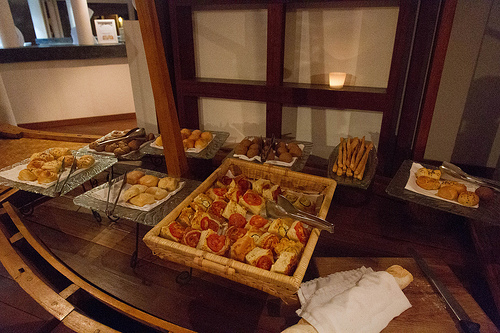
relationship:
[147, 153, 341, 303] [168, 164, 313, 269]
tray full of rolls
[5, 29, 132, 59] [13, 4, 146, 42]
counter in front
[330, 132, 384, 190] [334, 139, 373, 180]
tray of snacks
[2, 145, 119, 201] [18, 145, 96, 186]
tray of rolls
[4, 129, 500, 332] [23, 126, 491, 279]
table filled with bread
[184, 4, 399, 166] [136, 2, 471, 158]
window on wall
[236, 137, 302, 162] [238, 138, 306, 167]
brown colored bread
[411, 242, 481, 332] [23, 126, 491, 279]
knife to cut bread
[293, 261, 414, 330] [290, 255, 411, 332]
loaf of bread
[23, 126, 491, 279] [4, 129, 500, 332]
bread on table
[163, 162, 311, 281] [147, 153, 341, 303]
sandwiches in basket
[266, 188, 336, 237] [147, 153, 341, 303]
tong over basket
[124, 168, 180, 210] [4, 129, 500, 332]
baguette on table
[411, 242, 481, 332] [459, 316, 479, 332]
knife with handle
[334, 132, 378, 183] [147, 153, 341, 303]
bread behind basket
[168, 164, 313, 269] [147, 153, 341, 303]
food in basket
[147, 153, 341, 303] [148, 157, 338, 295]
basket made of wicker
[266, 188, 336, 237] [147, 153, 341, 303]
tongs in basket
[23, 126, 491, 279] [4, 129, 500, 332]
pastries on server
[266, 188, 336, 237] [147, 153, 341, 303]
tongs in server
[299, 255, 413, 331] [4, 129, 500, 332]
towel on table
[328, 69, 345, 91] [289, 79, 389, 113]
candle in shelf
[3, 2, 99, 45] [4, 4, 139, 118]
column in background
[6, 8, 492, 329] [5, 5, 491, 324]
photo was indoors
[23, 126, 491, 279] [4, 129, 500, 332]
buffet on table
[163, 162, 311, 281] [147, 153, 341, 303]
sandwiches on basket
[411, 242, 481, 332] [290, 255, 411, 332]
knife to cut bread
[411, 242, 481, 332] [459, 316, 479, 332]
knife has handle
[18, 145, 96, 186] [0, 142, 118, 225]
croissants on container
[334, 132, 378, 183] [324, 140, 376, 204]
bread on basket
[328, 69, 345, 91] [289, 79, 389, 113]
candle on shelf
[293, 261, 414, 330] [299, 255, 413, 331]
baguette with cloth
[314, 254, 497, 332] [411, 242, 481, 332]
board under knife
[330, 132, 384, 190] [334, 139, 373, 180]
plate of breadsticks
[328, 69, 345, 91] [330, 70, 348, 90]
candle in holder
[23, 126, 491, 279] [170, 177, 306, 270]
bread with tomato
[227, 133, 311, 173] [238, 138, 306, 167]
plate of bread